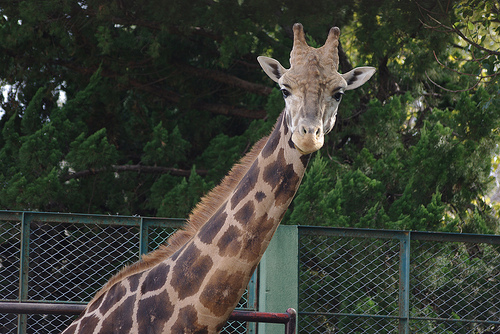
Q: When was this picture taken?
A: It was taken in the day time.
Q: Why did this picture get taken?
A: To show how the giraffe looks.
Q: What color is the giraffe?
A: The giraffe is brown.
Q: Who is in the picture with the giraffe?
A: Nobody is in the picture with the giraffe.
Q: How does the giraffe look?
A: The giraffe looks calm.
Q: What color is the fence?
A: The fence is green.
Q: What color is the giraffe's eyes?
A: The eyes are black.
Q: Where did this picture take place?
A: It took place in the day time.